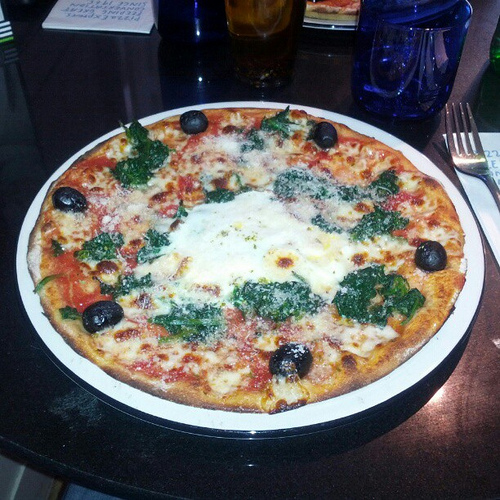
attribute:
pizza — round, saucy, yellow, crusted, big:
[34, 125, 472, 370]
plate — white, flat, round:
[14, 87, 489, 441]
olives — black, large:
[60, 108, 444, 380]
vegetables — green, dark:
[117, 136, 409, 328]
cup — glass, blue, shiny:
[353, 2, 476, 129]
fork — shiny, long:
[425, 97, 500, 229]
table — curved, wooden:
[2, 2, 499, 498]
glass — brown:
[213, 0, 314, 92]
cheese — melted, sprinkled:
[154, 191, 357, 302]